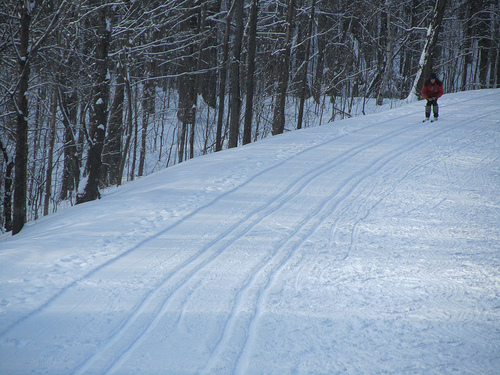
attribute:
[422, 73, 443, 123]
person — skiing, slouching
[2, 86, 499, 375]
snow — white, thick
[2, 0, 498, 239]
trees — brown, snow-covered, leafless, dead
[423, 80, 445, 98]
jacket — red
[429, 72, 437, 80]
hat — black